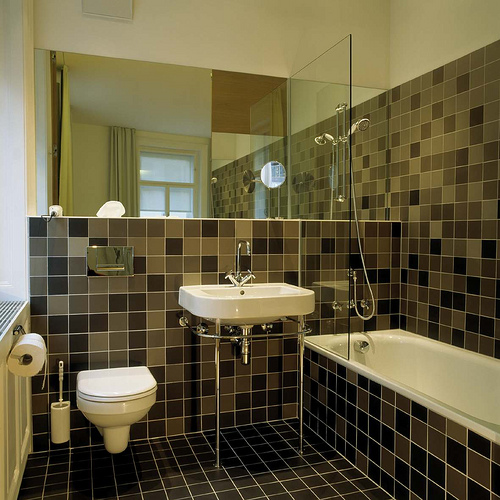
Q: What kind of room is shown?
A: It is a bathroom.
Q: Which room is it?
A: It is a bathroom.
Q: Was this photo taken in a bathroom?
A: Yes, it was taken in a bathroom.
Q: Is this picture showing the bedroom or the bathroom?
A: It is showing the bathroom.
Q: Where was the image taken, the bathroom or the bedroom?
A: It was taken at the bathroom.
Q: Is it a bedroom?
A: No, it is a bathroom.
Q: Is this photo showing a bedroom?
A: No, the picture is showing a bathroom.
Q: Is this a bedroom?
A: No, it is a bathroom.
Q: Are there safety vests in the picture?
A: No, there are no safety vests.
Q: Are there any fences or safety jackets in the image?
A: No, there are no safety jackets or fences.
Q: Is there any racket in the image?
A: No, there are no rackets.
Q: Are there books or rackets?
A: No, there are no rackets or books.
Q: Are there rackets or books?
A: No, there are no rackets or books.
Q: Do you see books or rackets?
A: No, there are no rackets or books.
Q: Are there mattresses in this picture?
A: No, there are no mattresses.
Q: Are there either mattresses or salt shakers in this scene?
A: No, there are no mattresses or salt shakers.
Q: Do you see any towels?
A: No, there are no towels.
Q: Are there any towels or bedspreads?
A: No, there are no towels or bedspreads.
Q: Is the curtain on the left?
A: Yes, the curtain is on the left of the image.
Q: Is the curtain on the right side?
A: No, the curtain is on the left of the image.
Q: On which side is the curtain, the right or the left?
A: The curtain is on the left of the image.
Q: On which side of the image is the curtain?
A: The curtain is on the left of the image.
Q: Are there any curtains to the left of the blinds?
A: Yes, there is a curtain to the left of the blinds.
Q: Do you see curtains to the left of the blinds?
A: Yes, there is a curtain to the left of the blinds.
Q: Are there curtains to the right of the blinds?
A: No, the curtain is to the left of the blinds.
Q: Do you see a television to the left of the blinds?
A: No, there is a curtain to the left of the blinds.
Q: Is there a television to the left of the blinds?
A: No, there is a curtain to the left of the blinds.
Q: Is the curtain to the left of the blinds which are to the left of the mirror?
A: Yes, the curtain is to the left of the blinds.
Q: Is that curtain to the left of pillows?
A: No, the curtain is to the left of the blinds.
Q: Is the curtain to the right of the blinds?
A: No, the curtain is to the left of the blinds.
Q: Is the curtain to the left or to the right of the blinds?
A: The curtain is to the left of the blinds.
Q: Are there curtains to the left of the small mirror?
A: Yes, there is a curtain to the left of the mirror.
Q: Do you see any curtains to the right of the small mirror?
A: No, the curtain is to the left of the mirror.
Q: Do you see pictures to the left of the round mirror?
A: No, there is a curtain to the left of the mirror.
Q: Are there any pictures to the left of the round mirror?
A: No, there is a curtain to the left of the mirror.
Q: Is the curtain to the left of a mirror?
A: Yes, the curtain is to the left of a mirror.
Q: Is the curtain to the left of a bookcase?
A: No, the curtain is to the left of a mirror.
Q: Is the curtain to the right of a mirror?
A: No, the curtain is to the left of a mirror.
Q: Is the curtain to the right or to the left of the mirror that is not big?
A: The curtain is to the left of the mirror.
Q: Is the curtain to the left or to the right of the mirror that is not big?
A: The curtain is to the left of the mirror.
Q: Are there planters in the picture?
A: No, there are no planters.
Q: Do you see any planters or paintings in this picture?
A: No, there are no planters or paintings.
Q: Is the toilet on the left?
A: Yes, the toilet is on the left of the image.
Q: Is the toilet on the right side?
A: No, the toilet is on the left of the image.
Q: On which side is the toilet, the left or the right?
A: The toilet is on the left of the image.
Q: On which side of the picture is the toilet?
A: The toilet is on the left of the image.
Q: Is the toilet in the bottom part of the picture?
A: Yes, the toilet is in the bottom of the image.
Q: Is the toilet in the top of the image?
A: No, the toilet is in the bottom of the image.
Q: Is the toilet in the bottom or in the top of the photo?
A: The toilet is in the bottom of the image.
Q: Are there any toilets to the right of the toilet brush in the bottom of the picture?
A: Yes, there is a toilet to the right of the toilet brush.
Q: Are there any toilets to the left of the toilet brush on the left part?
A: No, the toilet is to the right of the toilet brush.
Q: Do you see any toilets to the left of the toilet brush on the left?
A: No, the toilet is to the right of the toilet brush.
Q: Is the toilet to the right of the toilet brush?
A: Yes, the toilet is to the right of the toilet brush.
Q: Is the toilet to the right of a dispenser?
A: No, the toilet is to the right of the toilet brush.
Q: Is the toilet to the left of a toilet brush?
A: No, the toilet is to the right of a toilet brush.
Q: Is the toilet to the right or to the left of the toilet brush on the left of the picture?
A: The toilet is to the right of the toilet brush.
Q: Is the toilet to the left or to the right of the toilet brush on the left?
A: The toilet is to the right of the toilet brush.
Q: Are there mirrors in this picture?
A: Yes, there is a mirror.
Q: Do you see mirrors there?
A: Yes, there is a mirror.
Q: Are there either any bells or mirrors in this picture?
A: Yes, there is a mirror.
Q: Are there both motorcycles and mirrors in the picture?
A: No, there is a mirror but no motorcycles.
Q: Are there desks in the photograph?
A: No, there are no desks.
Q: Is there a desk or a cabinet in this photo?
A: No, there are no desks or cabinets.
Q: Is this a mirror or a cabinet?
A: This is a mirror.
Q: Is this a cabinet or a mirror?
A: This is a mirror.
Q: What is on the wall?
A: The mirror is on the wall.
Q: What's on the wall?
A: The mirror is on the wall.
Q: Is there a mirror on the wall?
A: Yes, there is a mirror on the wall.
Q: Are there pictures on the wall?
A: No, there is a mirror on the wall.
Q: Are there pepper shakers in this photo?
A: No, there are no pepper shakers.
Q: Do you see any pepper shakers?
A: No, there are no pepper shakers.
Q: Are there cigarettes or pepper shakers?
A: No, there are no pepper shakers or cigarettes.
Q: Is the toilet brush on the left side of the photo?
A: Yes, the toilet brush is on the left of the image.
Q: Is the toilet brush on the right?
A: No, the toilet brush is on the left of the image.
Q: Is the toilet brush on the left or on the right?
A: The toilet brush is on the left of the image.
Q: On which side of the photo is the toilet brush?
A: The toilet brush is on the left of the image.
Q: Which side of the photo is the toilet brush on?
A: The toilet brush is on the left of the image.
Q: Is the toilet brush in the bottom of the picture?
A: Yes, the toilet brush is in the bottom of the image.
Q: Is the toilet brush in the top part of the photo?
A: No, the toilet brush is in the bottom of the image.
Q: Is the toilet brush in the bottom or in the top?
A: The toilet brush is in the bottom of the image.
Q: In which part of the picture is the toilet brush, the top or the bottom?
A: The toilet brush is in the bottom of the image.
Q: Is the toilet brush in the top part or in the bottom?
A: The toilet brush is in the bottom of the image.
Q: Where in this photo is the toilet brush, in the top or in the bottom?
A: The toilet brush is in the bottom of the image.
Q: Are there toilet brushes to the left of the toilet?
A: Yes, there is a toilet brush to the left of the toilet.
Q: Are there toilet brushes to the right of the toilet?
A: No, the toilet brush is to the left of the toilet.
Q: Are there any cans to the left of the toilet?
A: No, there is a toilet brush to the left of the toilet.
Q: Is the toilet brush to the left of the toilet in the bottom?
A: Yes, the toilet brush is to the left of the toilet.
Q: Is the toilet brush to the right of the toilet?
A: No, the toilet brush is to the left of the toilet.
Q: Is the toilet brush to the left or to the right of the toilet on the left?
A: The toilet brush is to the left of the toilet.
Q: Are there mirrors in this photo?
A: Yes, there is a mirror.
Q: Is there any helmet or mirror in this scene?
A: Yes, there is a mirror.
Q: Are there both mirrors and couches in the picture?
A: No, there is a mirror but no couches.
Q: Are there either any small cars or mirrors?
A: Yes, there is a small mirror.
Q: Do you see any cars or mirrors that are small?
A: Yes, the mirror is small.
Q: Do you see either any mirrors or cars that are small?
A: Yes, the mirror is small.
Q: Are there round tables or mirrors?
A: Yes, there is a round mirror.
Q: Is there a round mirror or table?
A: Yes, there is a round mirror.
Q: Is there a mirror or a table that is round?
A: Yes, the mirror is round.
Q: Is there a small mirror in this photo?
A: Yes, there is a small mirror.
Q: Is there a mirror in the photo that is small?
A: Yes, there is a mirror that is small.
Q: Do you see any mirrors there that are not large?
A: Yes, there is a small mirror.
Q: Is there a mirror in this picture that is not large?
A: Yes, there is a small mirror.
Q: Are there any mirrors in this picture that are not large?
A: Yes, there is a small mirror.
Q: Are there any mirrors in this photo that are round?
A: Yes, there is a round mirror.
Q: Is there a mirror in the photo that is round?
A: Yes, there is a mirror that is round.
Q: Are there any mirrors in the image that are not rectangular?
A: Yes, there is a round mirror.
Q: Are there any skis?
A: No, there are no skis.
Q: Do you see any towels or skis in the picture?
A: No, there are no skis or towels.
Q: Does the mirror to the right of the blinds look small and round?
A: Yes, the mirror is small and round.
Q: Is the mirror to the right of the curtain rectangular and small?
A: No, the mirror is small but round.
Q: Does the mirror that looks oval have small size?
A: Yes, the mirror is small.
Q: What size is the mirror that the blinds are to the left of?
A: The mirror is small.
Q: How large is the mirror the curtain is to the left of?
A: The mirror is small.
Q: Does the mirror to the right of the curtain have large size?
A: No, the mirror is small.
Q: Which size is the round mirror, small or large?
A: The mirror is small.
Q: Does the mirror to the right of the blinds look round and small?
A: Yes, the mirror is round and small.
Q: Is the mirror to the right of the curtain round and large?
A: No, the mirror is round but small.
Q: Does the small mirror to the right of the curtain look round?
A: Yes, the mirror is round.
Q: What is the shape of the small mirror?
A: The mirror is round.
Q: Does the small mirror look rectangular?
A: No, the mirror is round.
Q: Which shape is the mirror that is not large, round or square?
A: The mirror is round.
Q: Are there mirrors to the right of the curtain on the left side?
A: Yes, there is a mirror to the right of the curtain.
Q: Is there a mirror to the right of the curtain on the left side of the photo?
A: Yes, there is a mirror to the right of the curtain.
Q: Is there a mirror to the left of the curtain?
A: No, the mirror is to the right of the curtain.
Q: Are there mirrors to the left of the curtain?
A: No, the mirror is to the right of the curtain.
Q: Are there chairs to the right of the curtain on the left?
A: No, there is a mirror to the right of the curtain.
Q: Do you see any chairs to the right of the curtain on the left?
A: No, there is a mirror to the right of the curtain.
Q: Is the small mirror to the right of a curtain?
A: Yes, the mirror is to the right of a curtain.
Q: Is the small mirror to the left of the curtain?
A: No, the mirror is to the right of the curtain.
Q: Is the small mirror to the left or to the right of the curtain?
A: The mirror is to the right of the curtain.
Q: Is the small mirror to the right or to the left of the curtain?
A: The mirror is to the right of the curtain.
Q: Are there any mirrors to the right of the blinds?
A: Yes, there is a mirror to the right of the blinds.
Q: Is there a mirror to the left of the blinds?
A: No, the mirror is to the right of the blinds.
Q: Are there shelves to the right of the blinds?
A: No, there is a mirror to the right of the blinds.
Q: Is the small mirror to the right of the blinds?
A: Yes, the mirror is to the right of the blinds.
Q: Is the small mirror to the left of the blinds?
A: No, the mirror is to the right of the blinds.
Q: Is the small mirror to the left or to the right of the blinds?
A: The mirror is to the right of the blinds.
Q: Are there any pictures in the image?
A: No, there are no pictures.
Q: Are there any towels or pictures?
A: No, there are no pictures or towels.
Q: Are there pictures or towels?
A: No, there are no pictures or towels.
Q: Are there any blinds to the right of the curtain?
A: Yes, there are blinds to the right of the curtain.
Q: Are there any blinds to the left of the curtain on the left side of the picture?
A: No, the blinds are to the right of the curtain.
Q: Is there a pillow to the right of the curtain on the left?
A: No, there are blinds to the right of the curtain.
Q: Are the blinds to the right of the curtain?
A: Yes, the blinds are to the right of the curtain.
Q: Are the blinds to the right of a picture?
A: No, the blinds are to the right of the curtain.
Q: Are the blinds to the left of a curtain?
A: No, the blinds are to the right of a curtain.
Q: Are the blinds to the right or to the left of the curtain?
A: The blinds are to the right of the curtain.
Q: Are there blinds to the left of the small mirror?
A: Yes, there are blinds to the left of the mirror.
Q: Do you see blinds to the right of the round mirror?
A: No, the blinds are to the left of the mirror.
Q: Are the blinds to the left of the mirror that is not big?
A: Yes, the blinds are to the left of the mirror.